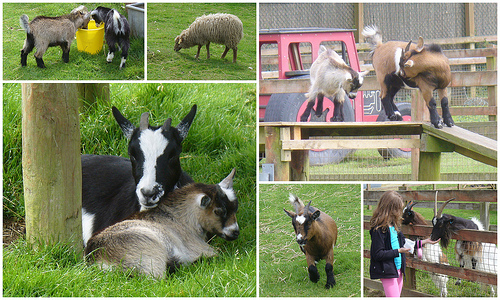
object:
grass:
[149, 2, 256, 80]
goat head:
[292, 212, 317, 245]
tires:
[264, 75, 356, 166]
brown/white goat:
[86, 168, 241, 282]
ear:
[176, 104, 197, 141]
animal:
[82, 104, 197, 247]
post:
[264, 126, 291, 181]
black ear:
[112, 106, 136, 141]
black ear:
[283, 208, 296, 218]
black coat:
[369, 223, 424, 282]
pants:
[380, 269, 404, 298]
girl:
[370, 190, 443, 297]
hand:
[400, 247, 412, 254]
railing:
[258, 121, 498, 181]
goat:
[361, 25, 455, 129]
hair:
[369, 190, 404, 232]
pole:
[21, 83, 85, 257]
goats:
[173, 13, 243, 63]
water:
[76, 20, 106, 54]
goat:
[300, 45, 369, 122]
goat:
[403, 200, 450, 298]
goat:
[431, 197, 499, 297]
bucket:
[76, 20, 105, 55]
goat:
[284, 192, 338, 288]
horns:
[303, 201, 311, 221]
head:
[128, 124, 184, 208]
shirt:
[389, 226, 402, 270]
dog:
[20, 5, 91, 68]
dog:
[83, 6, 130, 71]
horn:
[139, 112, 150, 131]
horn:
[161, 118, 172, 132]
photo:
[0, 1, 500, 299]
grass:
[267, 260, 298, 295]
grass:
[33, 237, 161, 297]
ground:
[17, 218, 126, 296]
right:
[162, 95, 232, 175]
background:
[268, 9, 404, 172]